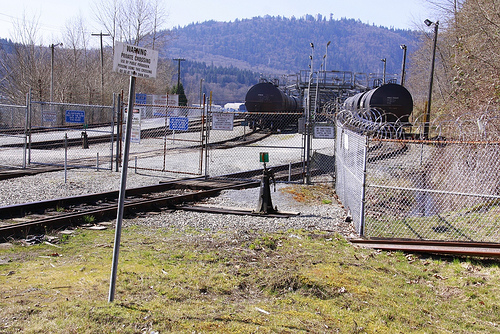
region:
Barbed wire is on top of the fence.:
[377, 107, 459, 163]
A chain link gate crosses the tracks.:
[183, 83, 321, 260]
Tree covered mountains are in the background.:
[227, 10, 369, 60]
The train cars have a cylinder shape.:
[348, 76, 444, 154]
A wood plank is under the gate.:
[170, 152, 248, 206]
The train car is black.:
[242, 75, 291, 143]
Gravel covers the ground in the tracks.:
[148, 137, 221, 171]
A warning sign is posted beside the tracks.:
[104, 26, 216, 295]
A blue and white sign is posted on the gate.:
[157, 100, 207, 182]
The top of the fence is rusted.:
[355, 104, 434, 166]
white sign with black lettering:
[100, 35, 172, 85]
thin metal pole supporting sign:
[105, 67, 142, 312]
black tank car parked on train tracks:
[330, 70, 421, 145]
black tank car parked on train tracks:
[239, 71, 305, 134]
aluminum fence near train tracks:
[1, 82, 496, 249]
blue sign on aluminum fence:
[62, 105, 84, 127]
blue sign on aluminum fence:
[166, 114, 194, 134]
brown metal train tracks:
[2, 126, 412, 246]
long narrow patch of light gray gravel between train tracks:
[1, 100, 383, 215]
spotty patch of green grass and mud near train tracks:
[1, 221, 498, 332]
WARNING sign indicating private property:
[110, 36, 162, 81]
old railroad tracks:
[2, 173, 215, 247]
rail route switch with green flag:
[254, 146, 281, 219]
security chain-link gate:
[29, 93, 206, 173]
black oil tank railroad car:
[241, 76, 304, 136]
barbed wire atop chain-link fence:
[327, 102, 496, 144]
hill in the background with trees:
[159, 19, 384, 72]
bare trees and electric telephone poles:
[2, 1, 113, 98]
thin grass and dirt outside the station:
[126, 228, 338, 330]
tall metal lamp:
[422, 16, 438, 139]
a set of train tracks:
[2, 138, 399, 245]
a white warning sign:
[103, 31, 161, 306]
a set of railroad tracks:
[1, 122, 272, 180]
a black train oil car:
[235, 77, 296, 130]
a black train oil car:
[359, 82, 412, 132]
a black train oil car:
[336, 89, 361, 118]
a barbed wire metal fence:
[333, 98, 499, 245]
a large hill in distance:
[102, 9, 433, 88]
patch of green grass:
[9, 226, 489, 332]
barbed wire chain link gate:
[31, 92, 204, 178]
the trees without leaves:
[4, 19, 146, 99]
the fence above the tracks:
[8, 100, 498, 246]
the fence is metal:
[1, 92, 492, 238]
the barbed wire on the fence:
[315, 94, 499, 145]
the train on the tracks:
[213, 74, 304, 130]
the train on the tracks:
[333, 74, 418, 130]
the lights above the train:
[373, 13, 442, 64]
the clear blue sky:
[188, 1, 248, 11]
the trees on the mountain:
[223, 25, 300, 82]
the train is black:
[233, 73, 403, 133]